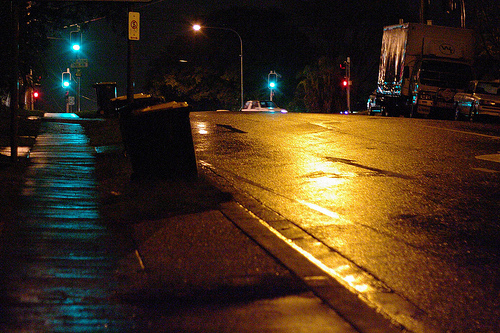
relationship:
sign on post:
[127, 12, 141, 42] [129, 1, 136, 117]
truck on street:
[377, 23, 474, 119] [188, 110, 499, 332]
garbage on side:
[129, 100, 200, 187] [0, 107, 404, 331]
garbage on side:
[92, 81, 115, 114] [0, 107, 404, 331]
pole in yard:
[9, 2, 21, 159] [0, 110, 43, 203]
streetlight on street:
[192, 23, 244, 113] [188, 110, 499, 332]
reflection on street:
[303, 155, 346, 186] [188, 110, 499, 332]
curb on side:
[220, 199, 384, 332] [0, 107, 404, 331]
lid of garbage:
[129, 99, 188, 117] [129, 100, 200, 187]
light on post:
[72, 42, 81, 52] [75, 24, 82, 115]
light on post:
[267, 81, 277, 90] [267, 70, 278, 103]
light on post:
[63, 79, 70, 90] [62, 68, 71, 114]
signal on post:
[337, 62, 346, 70] [343, 55, 351, 111]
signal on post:
[266, 72, 277, 93] [267, 70, 278, 103]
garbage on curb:
[129, 100, 200, 187] [197, 164, 233, 212]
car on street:
[455, 78, 499, 121] [188, 110, 499, 332]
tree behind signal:
[300, 57, 341, 113] [337, 62, 346, 70]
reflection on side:
[63, 112, 77, 120] [0, 107, 404, 331]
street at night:
[188, 110, 499, 332] [41, 1, 241, 111]